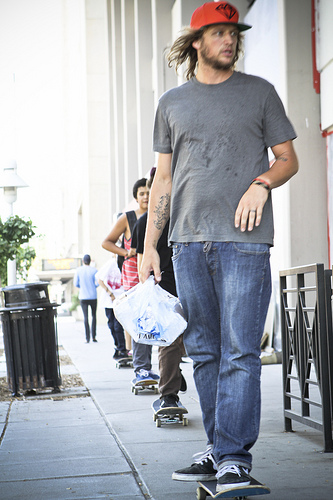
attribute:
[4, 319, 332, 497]
sidewalk — concrete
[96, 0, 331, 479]
line — men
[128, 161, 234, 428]
man — skateboarding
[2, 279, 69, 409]
trashcan — black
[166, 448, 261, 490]
tennis shoes — white, black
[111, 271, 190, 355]
bag — whjite, paper, small, plastic, grocery bag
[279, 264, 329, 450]
gate — metal, open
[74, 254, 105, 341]
man — walking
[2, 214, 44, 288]
tree — growing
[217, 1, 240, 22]
drawing — diamond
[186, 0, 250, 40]
hat — red, black, orange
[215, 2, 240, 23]
diamond — black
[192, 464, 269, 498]
skateboard — black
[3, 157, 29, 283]
street light — white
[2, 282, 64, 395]
garbage can — brown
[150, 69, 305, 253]
tshirt — grey, gray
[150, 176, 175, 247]
forearm — man's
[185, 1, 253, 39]
cap — orange, red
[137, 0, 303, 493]
man — holding, skateboarding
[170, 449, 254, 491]
sneakers — blue, white, black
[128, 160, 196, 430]
guy — skateboarding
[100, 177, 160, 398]
guy — skateboarding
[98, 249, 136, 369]
guy — skateboarding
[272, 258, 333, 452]
fence — black, iron, small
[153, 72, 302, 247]
shirt — blue, gray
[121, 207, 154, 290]
shirt — striped, red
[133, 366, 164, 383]
shoes — skateboarding shoes, blue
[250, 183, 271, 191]
bracelet — rubber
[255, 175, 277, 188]
bracelet — rubber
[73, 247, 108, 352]
person — walking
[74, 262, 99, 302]
tshirt — baby blue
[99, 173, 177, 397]
man — skateboarding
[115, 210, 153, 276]
backpack — black